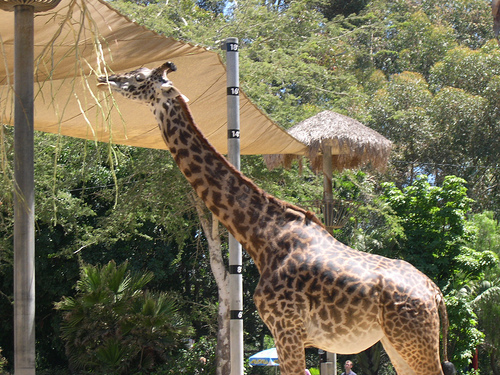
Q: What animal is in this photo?
A: Giraffe.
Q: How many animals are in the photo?
A: 1.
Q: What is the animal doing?
A: Eating.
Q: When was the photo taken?
A: Daytime.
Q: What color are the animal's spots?
A: Brown.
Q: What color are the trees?
A: Green.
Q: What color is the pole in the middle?
A: Silver.